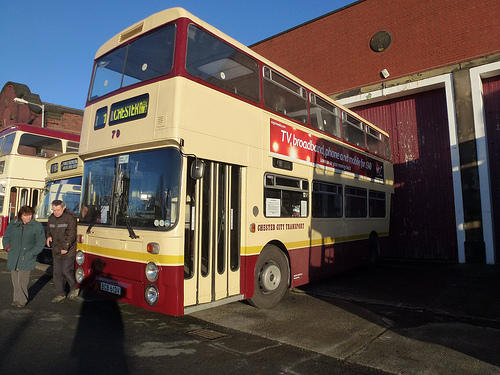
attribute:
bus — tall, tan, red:
[73, 5, 400, 318]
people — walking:
[0, 197, 95, 324]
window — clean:
[83, 143, 182, 233]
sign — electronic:
[112, 100, 147, 121]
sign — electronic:
[269, 118, 384, 180]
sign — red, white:
[253, 111, 403, 186]